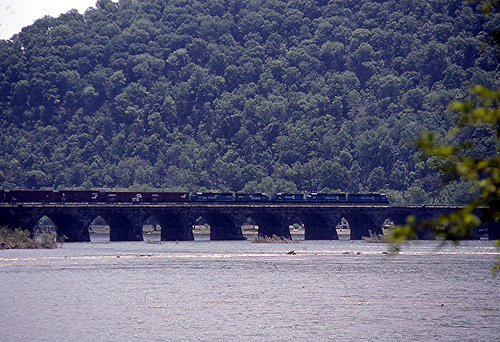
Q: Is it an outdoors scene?
A: Yes, it is outdoors.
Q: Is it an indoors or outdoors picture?
A: It is outdoors.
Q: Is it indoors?
A: No, it is outdoors.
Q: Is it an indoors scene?
A: No, it is outdoors.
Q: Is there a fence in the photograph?
A: No, there are no fences.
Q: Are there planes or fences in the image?
A: No, there are no fences or planes.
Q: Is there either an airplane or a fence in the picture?
A: No, there are no fences or airplanes.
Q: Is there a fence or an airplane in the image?
A: No, there are no fences or airplanes.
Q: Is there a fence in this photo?
A: No, there are no fences.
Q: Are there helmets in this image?
A: No, there are no helmets.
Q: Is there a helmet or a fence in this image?
A: No, there are no helmets or fences.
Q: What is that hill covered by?
A: The hill is covered by the trees.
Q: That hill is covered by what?
A: The hill is covered by the trees.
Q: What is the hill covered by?
A: The hill is covered by the trees.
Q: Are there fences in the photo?
A: No, there are no fences.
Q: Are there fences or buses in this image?
A: No, there are no fences or buses.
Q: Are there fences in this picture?
A: No, there are no fences.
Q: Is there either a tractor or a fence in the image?
A: No, there are no fences or tractors.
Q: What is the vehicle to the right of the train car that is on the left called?
A: The vehicle is a car.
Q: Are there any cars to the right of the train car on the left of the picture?
A: Yes, there is a car to the right of the train car.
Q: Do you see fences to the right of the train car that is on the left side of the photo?
A: No, there is a car to the right of the train car.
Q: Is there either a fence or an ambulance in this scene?
A: No, there are no fences or ambulances.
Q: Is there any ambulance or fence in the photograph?
A: No, there are no fences or ambulances.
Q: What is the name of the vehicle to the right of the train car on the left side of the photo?
A: The vehicle is a car.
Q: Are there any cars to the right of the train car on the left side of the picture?
A: Yes, there is a car to the right of the train car.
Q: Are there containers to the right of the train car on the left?
A: No, there is a car to the right of the train car.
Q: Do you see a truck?
A: No, there are no trucks.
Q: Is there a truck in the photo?
A: No, there are no trucks.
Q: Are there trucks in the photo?
A: No, there are no trucks.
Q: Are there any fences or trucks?
A: No, there are no trucks or fences.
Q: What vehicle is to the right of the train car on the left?
A: The vehicle is a car.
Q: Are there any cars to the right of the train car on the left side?
A: Yes, there is a car to the right of the train car.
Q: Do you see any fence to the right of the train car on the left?
A: No, there is a car to the right of the train car.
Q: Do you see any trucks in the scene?
A: No, there are no trucks.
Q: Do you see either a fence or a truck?
A: No, there are no trucks or fences.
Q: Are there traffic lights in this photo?
A: No, there are no traffic lights.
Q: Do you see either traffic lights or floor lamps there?
A: No, there are no traffic lights or floor lamps.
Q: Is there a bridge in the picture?
A: Yes, there is a bridge.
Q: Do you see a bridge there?
A: Yes, there is a bridge.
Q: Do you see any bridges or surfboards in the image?
A: Yes, there is a bridge.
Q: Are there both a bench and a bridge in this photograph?
A: No, there is a bridge but no benches.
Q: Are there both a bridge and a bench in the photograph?
A: No, there is a bridge but no benches.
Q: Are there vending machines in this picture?
A: No, there are no vending machines.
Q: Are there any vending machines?
A: No, there are no vending machines.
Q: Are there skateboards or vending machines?
A: No, there are no vending machines or skateboards.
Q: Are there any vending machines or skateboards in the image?
A: No, there are no vending machines or skateboards.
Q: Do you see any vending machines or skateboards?
A: No, there are no vending machines or skateboards.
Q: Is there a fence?
A: No, there are no fences.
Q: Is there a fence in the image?
A: No, there are no fences.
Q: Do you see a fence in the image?
A: No, there are no fences.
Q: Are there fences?
A: No, there are no fences.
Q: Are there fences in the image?
A: No, there are no fences.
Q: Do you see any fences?
A: No, there are no fences.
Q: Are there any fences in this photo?
A: No, there are no fences.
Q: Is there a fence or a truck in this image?
A: No, there are no fences or trucks.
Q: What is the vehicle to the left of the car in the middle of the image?
A: The vehicle is a train car.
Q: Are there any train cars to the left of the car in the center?
A: Yes, there is a train car to the left of the car.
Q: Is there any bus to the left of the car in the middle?
A: No, there is a train car to the left of the car.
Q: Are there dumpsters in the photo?
A: No, there are no dumpsters.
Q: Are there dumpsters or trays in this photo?
A: No, there are no dumpsters or trays.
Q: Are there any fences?
A: No, there are no fences.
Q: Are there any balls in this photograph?
A: No, there are no balls.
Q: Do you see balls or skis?
A: No, there are no balls or skis.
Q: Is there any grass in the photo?
A: Yes, there is grass.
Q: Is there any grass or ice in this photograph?
A: Yes, there is grass.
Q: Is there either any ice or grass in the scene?
A: Yes, there is grass.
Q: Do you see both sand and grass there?
A: No, there is grass but no sand.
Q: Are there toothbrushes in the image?
A: No, there are no toothbrushes.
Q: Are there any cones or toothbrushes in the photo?
A: No, there are no toothbrushes or cones.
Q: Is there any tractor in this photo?
A: No, there are no tractors.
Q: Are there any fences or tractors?
A: No, there are no tractors or fences.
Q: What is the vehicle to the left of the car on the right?
A: The vehicle is a train car.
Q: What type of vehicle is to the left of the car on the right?
A: The vehicle is a train car.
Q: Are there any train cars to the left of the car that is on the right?
A: Yes, there is a train car to the left of the car.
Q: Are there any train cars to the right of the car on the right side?
A: No, the train car is to the left of the car.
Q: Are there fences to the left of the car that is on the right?
A: No, there is a train car to the left of the car.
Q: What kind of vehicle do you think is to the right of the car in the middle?
A: The vehicle is a train car.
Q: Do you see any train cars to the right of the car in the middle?
A: Yes, there is a train car to the right of the car.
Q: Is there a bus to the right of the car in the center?
A: No, there is a train car to the right of the car.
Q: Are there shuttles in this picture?
A: No, there are no shuttles.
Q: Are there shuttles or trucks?
A: No, there are no shuttles or trucks.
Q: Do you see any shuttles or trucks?
A: No, there are no shuttles or trucks.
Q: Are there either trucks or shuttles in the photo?
A: No, there are no shuttles or trucks.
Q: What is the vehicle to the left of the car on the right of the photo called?
A: The vehicle is a train car.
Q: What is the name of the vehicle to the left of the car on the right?
A: The vehicle is a train car.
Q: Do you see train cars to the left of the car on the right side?
A: Yes, there is a train car to the left of the car.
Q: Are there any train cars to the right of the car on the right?
A: No, the train car is to the left of the car.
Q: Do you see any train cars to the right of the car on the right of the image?
A: No, the train car is to the left of the car.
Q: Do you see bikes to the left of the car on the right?
A: No, there is a train car to the left of the car.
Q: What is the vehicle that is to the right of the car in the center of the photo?
A: The vehicle is a train car.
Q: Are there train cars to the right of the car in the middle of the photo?
A: Yes, there is a train car to the right of the car.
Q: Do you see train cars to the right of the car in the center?
A: Yes, there is a train car to the right of the car.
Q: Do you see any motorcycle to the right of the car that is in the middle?
A: No, there is a train car to the right of the car.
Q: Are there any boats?
A: No, there are no boats.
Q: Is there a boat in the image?
A: No, there are no boats.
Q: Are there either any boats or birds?
A: No, there are no boats or birds.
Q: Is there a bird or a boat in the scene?
A: No, there are no boats or birds.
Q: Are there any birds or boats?
A: No, there are no boats or birds.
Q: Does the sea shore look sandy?
A: Yes, the sea shore is sandy.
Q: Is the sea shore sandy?
A: Yes, the sea shore is sandy.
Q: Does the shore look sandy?
A: Yes, the shore is sandy.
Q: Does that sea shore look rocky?
A: No, the sea shore is sandy.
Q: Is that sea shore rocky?
A: No, the sea shore is sandy.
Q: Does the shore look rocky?
A: No, the shore is sandy.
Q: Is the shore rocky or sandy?
A: The shore is sandy.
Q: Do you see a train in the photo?
A: Yes, there is a train.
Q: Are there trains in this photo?
A: Yes, there is a train.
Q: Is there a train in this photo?
A: Yes, there is a train.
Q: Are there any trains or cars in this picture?
A: Yes, there is a train.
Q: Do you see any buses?
A: No, there are no buses.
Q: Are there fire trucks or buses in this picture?
A: No, there are no buses or fire trucks.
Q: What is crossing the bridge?
A: The train is crossing the bridge.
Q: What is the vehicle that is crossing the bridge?
A: The vehicle is a train.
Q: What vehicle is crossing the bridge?
A: The vehicle is a train.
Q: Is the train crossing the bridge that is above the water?
A: Yes, the train is crossing the bridge.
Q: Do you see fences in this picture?
A: No, there are no fences.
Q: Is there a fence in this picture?
A: No, there are no fences.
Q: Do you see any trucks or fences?
A: No, there are no fences or trucks.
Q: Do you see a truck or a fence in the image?
A: No, there are no fences or trucks.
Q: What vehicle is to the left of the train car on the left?
A: The vehicle is a car.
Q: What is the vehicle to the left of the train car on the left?
A: The vehicle is a car.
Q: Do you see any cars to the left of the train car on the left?
A: Yes, there is a car to the left of the train car.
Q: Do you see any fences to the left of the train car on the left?
A: No, there is a car to the left of the train car.